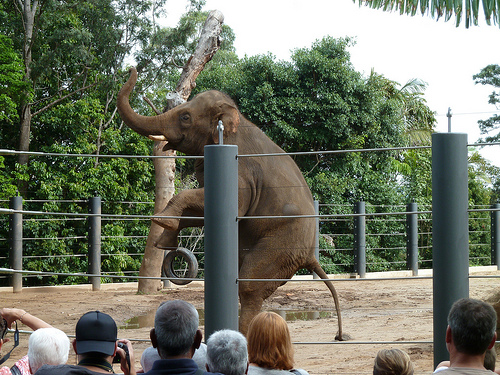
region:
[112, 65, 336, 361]
elephant standing on its hind legs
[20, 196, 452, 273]
fence with thick metal poles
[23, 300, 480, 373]
group of people watching the elephant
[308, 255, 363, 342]
thin tail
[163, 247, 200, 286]
small rubber tire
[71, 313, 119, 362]
black baseball cap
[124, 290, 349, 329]
large puddle in the dirt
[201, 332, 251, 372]
man with white hair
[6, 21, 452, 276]
wooded area on the other side of the fence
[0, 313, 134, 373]
people taking pictures of the elephant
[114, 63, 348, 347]
An elephant in a zoo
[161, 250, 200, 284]
A hanging automobile tire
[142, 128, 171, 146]
The white tusk of an elephant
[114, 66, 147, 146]
The trunk of an elephant raised up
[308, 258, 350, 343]
The tail of an elephant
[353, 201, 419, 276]
The iron fence of a zoo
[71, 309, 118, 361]
A man wearing a cap front to back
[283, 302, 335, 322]
A pool of stagnant water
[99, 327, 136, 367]
Using a camera to take photos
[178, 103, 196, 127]
The eye of an elephant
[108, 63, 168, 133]
long trunk of elephant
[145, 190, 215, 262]
large legs of elephant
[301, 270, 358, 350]
long brown tail of elephant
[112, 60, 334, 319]
elephant standing on legs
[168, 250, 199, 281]
black tire swing hanging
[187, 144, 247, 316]
tall metal post for fence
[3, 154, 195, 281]
grey metal wires on fence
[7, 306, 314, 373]
crowd standing together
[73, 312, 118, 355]
black hat backwards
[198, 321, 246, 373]
grey hair on mans head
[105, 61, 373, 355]
an elephant performing for a crowd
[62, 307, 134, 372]
a black hat worn backwards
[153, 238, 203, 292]
a tire hanging from tree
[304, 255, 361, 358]
a tail of the elephant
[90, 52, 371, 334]
a brown elephant standing on two legs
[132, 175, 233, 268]
both front feet in the air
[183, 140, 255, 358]
a gray pole holding wires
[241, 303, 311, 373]
A woman has light brown hair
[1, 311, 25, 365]
a black strap from a camera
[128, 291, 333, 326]
a small puddle in the dirt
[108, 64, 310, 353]
a elephant standing on hind legs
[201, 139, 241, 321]
a metal post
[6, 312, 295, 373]
people watching the elephant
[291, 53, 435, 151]
trees behind the fence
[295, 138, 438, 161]
cable on fence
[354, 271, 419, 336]
sand in the park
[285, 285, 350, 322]
a water hole behind elephant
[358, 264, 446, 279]
concert holding post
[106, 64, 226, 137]
elephants trunk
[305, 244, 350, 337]
elephants tail